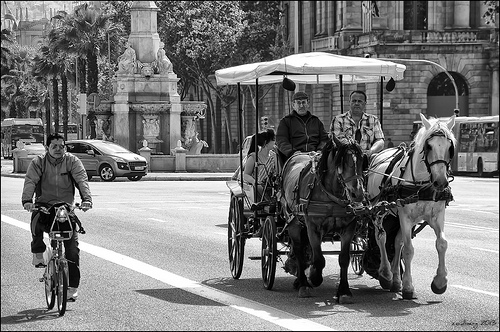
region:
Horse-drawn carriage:
[214, 46, 404, 289]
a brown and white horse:
[275, 128, 376, 303]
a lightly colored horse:
[352, 102, 477, 302]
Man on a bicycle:
[18, 127, 97, 317]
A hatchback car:
[43, 123, 150, 190]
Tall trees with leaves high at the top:
[40, 8, 272, 167]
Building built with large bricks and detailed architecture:
[212, 2, 497, 163]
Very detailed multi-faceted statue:
[78, 4, 209, 169]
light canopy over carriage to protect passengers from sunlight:
[215, 48, 409, 88]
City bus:
[454, 118, 498, 178]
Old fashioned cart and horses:
[209, 45, 454, 304]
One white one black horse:
[306, 125, 455, 304]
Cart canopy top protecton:
[209, 39, 409, 116]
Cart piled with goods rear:
[224, 76, 276, 240]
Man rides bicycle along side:
[17, 133, 91, 322]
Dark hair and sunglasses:
[30, 126, 80, 191]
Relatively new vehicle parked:
[64, 135, 171, 197]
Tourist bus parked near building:
[424, 109, 498, 196]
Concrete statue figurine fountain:
[115, 1, 202, 153]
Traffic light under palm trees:
[69, 11, 92, 141]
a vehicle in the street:
[53, 130, 144, 187]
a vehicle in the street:
[20, 197, 85, 312]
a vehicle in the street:
[219, 165, 402, 291]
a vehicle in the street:
[417, 108, 499, 182]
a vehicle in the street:
[0, 110, 40, 159]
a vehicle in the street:
[51, 120, 83, 144]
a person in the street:
[18, 130, 92, 290]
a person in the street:
[239, 121, 278, 206]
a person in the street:
[281, 90, 333, 163]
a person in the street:
[333, 84, 388, 166]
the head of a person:
[40, 132, 69, 159]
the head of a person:
[289, 90, 309, 112]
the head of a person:
[347, 85, 365, 109]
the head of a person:
[249, 127, 279, 156]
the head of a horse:
[325, 132, 376, 214]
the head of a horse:
[406, 100, 468, 200]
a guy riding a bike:
[27, 129, 98, 322]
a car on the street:
[47, 122, 151, 182]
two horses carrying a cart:
[282, 96, 472, 302]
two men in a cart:
[276, 88, 391, 180]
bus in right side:
[409, 111, 496, 171]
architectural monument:
[69, 0, 211, 175]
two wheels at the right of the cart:
[212, 191, 297, 284]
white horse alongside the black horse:
[365, 112, 467, 301]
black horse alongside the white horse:
[280, 135, 370, 296]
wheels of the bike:
[40, 251, 75, 321]